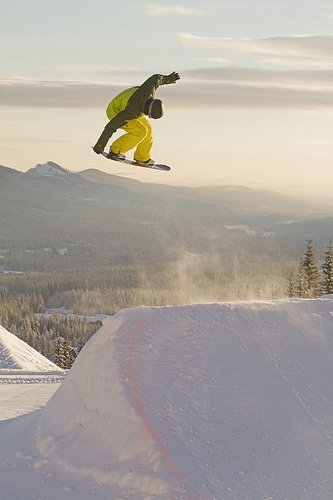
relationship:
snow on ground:
[1, 413, 46, 463] [6, 373, 89, 500]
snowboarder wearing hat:
[84, 66, 193, 184] [140, 97, 162, 116]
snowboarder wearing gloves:
[84, 66, 193, 184] [164, 68, 186, 89]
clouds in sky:
[226, 23, 332, 64] [4, 10, 319, 112]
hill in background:
[0, 158, 332, 284] [3, 5, 332, 303]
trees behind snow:
[12, 319, 96, 366] [1, 413, 46, 463]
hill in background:
[11, 238, 160, 285] [3, 5, 332, 303]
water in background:
[43, 296, 105, 329] [3, 5, 332, 303]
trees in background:
[12, 319, 96, 366] [3, 5, 332, 303]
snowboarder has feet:
[84, 66, 193, 184] [103, 144, 161, 176]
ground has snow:
[6, 373, 89, 500] [1, 413, 46, 463]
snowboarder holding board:
[84, 66, 193, 184] [74, 140, 173, 191]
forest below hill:
[8, 278, 93, 312] [0, 158, 332, 284]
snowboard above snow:
[101, 148, 184, 182] [1, 413, 46, 463]